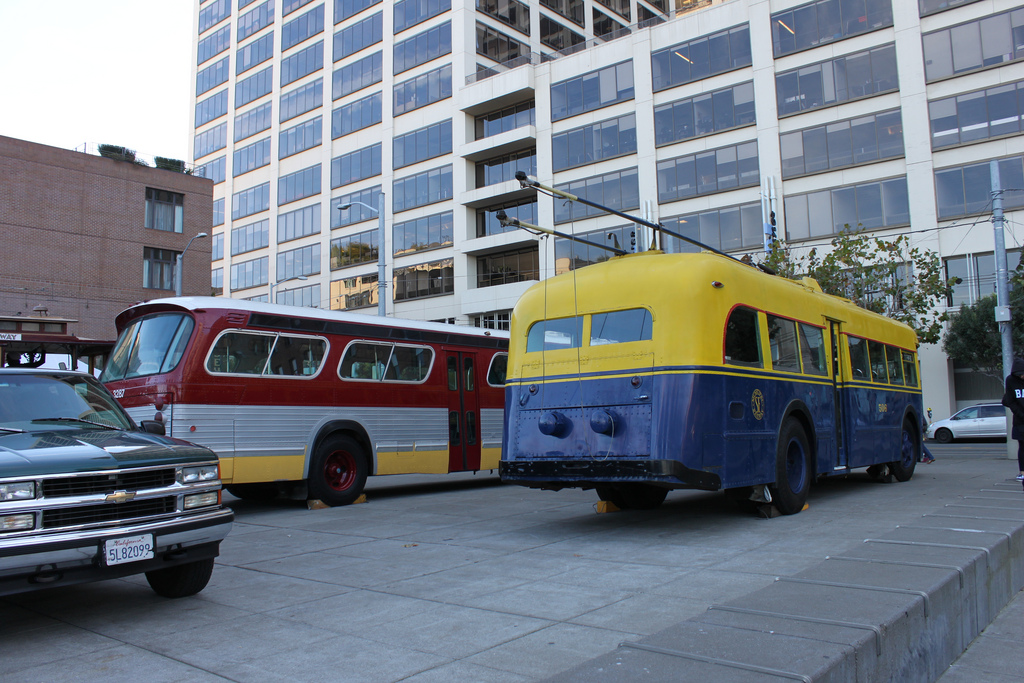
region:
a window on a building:
[536, 66, 636, 117]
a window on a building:
[654, 37, 765, 82]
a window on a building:
[779, 54, 912, 118]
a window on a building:
[767, 117, 917, 179]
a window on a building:
[773, 181, 928, 240]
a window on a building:
[551, 116, 654, 165]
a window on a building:
[647, 88, 764, 134]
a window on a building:
[631, 151, 796, 206]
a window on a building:
[390, 117, 457, 171]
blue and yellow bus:
[500, 241, 931, 549]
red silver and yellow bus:
[98, 307, 494, 494]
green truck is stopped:
[7, 350, 197, 622]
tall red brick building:
[4, 173, 219, 344]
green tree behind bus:
[739, 211, 987, 348]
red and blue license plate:
[98, 528, 157, 567]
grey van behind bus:
[926, 389, 999, 448]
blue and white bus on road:
[487, 237, 937, 523]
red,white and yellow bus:
[96, 288, 512, 516]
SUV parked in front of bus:
[0, 360, 241, 607]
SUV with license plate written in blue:
[0, 353, 248, 617]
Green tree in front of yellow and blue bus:
[485, 214, 961, 522]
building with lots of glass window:
[181, 0, 1017, 425]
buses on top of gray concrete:
[0, 239, 1016, 673]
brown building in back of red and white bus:
[0, 123, 510, 493]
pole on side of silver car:
[914, 142, 1019, 465]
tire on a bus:
[762, 419, 843, 511]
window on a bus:
[497, 308, 584, 357]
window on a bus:
[203, 332, 339, 419]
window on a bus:
[332, 330, 453, 414]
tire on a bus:
[272, 419, 406, 497]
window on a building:
[260, 155, 343, 213]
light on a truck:
[146, 449, 235, 517]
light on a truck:
[7, 466, 56, 546]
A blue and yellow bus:
[493, 251, 937, 524]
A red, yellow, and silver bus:
[88, 286, 513, 502]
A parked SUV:
[6, 356, 229, 623]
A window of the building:
[139, 182, 190, 234]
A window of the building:
[139, 239, 187, 291]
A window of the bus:
[204, 321, 275, 378]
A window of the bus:
[272, 320, 327, 390]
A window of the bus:
[521, 306, 582, 352]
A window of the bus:
[593, 308, 657, 344]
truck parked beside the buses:
[6, 366, 232, 607]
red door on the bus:
[443, 345, 485, 472]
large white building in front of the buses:
[189, 7, 1016, 404]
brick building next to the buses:
[8, 151, 220, 363]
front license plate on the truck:
[95, 525, 153, 563]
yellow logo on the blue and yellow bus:
[748, 382, 769, 412]